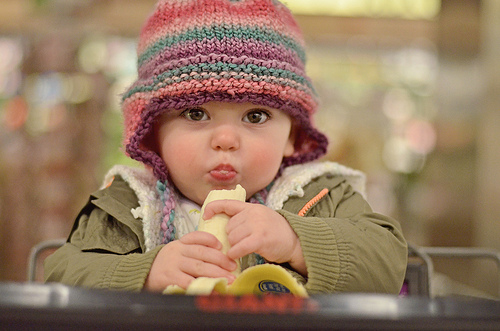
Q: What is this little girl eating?
A: A banana.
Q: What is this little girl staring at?
A: The camera.